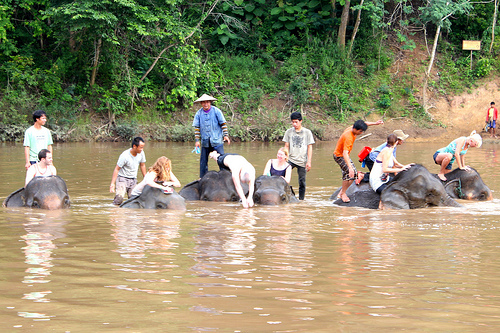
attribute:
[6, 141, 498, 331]
river — muddy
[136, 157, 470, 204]
elephants — grouped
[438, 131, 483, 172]
girl — starting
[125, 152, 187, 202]
girl — red haired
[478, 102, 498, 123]
jacket — red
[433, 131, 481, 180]
girl — blonde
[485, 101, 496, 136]
man — standing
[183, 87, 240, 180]
man — wearing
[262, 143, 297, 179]
women — sitting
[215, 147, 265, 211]
person — diving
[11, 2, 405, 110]
trees — along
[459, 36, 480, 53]
sign — yellow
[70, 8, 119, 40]
leaves — green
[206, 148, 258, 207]
man — diving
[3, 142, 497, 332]
water — brown